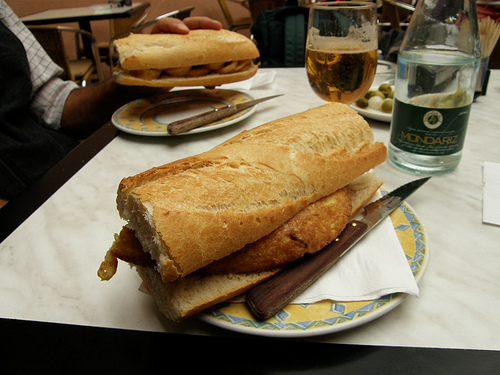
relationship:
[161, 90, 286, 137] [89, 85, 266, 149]
knife on plate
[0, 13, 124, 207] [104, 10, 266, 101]
man holding sandwich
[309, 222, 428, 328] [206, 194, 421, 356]
napkin on plate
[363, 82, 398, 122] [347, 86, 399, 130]
olives on plate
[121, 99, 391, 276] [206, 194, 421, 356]
sandwich on plate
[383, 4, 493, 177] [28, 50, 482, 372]
bottle on table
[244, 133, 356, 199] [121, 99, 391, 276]
crust on bread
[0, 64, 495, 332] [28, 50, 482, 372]
paper on table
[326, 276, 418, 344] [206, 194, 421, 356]
edge of plate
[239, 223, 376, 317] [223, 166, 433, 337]
handle of knife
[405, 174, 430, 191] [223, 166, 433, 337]
tip of knife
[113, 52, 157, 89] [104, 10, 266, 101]
edge of sandwich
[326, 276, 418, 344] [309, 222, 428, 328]
edge of napkin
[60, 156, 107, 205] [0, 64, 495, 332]
edge of paper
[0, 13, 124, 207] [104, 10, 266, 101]
man with sandwich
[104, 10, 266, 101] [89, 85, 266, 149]
sandwich on plate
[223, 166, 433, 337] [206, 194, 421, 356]
knife on plate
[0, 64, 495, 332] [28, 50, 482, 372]
paper covers table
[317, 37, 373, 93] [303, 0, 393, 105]
beverage in glass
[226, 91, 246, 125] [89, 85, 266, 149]
design on plate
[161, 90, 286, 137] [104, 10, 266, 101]
knife by sandwich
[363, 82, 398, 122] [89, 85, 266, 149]
olives on plate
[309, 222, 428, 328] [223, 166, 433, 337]
napkin under knife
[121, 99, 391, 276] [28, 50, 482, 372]
sandwich on table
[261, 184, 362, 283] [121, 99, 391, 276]
meat on sandwich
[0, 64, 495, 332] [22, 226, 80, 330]
paper covering table